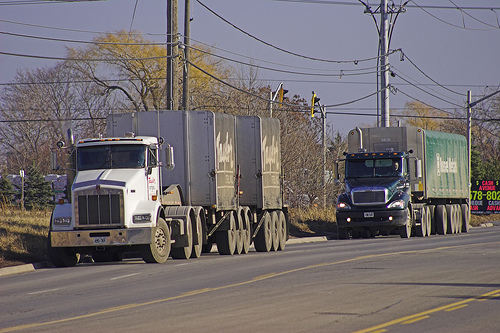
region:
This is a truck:
[23, 99, 320, 280]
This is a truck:
[309, 109, 481, 245]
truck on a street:
[325, 116, 482, 251]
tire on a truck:
[435, 205, 445, 230]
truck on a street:
[40, 85, 300, 290]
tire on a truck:
[142, 215, 169, 270]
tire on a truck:
[215, 211, 235, 261]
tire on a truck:
[255, 210, 276, 255]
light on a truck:
[50, 211, 73, 229]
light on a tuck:
[121, 203, 154, 223]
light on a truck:
[335, 196, 350, 216]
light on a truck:
[384, 192, 414, 213]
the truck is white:
[52, 131, 185, 261]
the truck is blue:
[314, 133, 412, 255]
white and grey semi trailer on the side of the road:
[48, 90, 300, 271]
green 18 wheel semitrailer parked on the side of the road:
[336, 110, 478, 240]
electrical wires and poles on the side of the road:
[5, 10, 492, 100]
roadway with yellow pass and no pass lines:
[1, 225, 498, 332]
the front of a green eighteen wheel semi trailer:
[334, 143, 413, 243]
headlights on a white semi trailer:
[42, 210, 156, 232]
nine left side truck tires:
[147, 204, 292, 264]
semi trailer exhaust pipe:
[52, 126, 80, 210]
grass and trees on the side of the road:
[5, 90, 47, 313]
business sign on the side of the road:
[470, 168, 499, 247]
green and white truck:
[420, 129, 477, 200]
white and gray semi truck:
[98, 138, 270, 243]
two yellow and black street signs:
[207, 81, 336, 188]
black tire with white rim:
[125, 213, 177, 291]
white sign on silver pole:
[6, 158, 29, 203]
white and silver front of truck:
[29, 135, 167, 322]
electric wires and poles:
[172, 65, 469, 146]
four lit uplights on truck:
[247, 195, 410, 260]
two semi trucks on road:
[118, 109, 433, 255]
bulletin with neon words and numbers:
[411, 165, 496, 270]